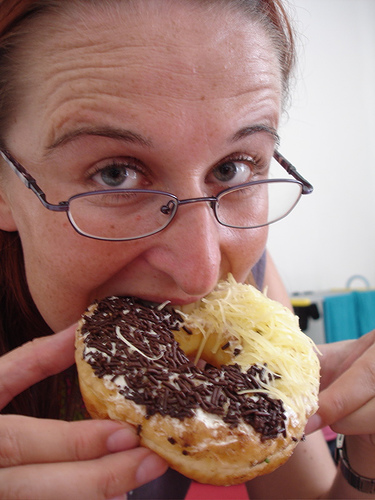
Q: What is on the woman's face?
A: Glasses.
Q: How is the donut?
A: Loaded.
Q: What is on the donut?
A: Sprinkles.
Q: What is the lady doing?
A: Biting.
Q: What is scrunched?
A: Lady's forehead.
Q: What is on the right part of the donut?
A: Coconut.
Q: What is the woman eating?
A: A doughnut.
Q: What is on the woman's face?
A: Glasses.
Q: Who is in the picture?
A: A woman.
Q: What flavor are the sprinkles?
A: Chocolate.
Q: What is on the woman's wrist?
A: A watch.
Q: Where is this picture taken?
A: A doughnut shop.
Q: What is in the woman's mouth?
A: A doughnut.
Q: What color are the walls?
A: White.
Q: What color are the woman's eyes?
A: Brown.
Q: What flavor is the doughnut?
A: Coconut and chocolate.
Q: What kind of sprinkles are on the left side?
A: Chocolate.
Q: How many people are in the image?
A: 1.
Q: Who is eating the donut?
A: The woman with glasses.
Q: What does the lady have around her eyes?
A: Glasses.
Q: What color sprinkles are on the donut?
A: Black and light yellow.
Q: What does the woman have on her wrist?
A: Watch.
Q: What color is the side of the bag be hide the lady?
A: Blue.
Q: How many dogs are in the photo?
A: 0.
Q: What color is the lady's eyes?
A: Blue.